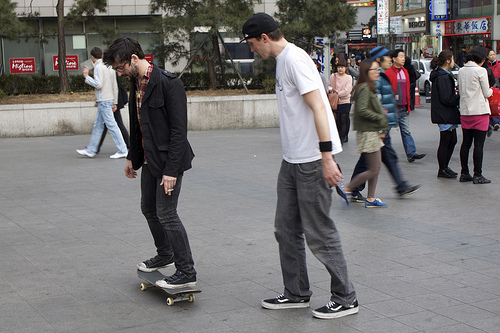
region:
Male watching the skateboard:
[239, 13, 368, 316]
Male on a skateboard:
[102, 38, 200, 305]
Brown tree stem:
[51, 0, 73, 94]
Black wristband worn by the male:
[318, 135, 333, 154]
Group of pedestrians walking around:
[329, 47, 498, 207]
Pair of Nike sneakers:
[261, 290, 361, 318]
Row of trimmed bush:
[1, 68, 217, 95]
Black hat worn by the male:
[239, 13, 283, 43]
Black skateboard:
[134, 263, 199, 303]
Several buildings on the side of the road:
[311, 0, 498, 75]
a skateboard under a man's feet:
[131, 266, 199, 307]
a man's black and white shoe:
[157, 268, 198, 290]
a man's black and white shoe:
[308, 300, 358, 318]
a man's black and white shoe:
[260, 293, 309, 310]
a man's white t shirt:
[278, 43, 343, 163]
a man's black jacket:
[117, 70, 193, 170]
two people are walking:
[78, 47, 127, 157]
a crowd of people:
[331, 46, 496, 208]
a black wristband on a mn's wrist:
[318, 141, 332, 152]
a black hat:
[233, 13, 279, 40]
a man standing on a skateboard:
[101, 36, 204, 308]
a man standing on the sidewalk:
[237, 8, 366, 321]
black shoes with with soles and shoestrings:
[255, 286, 373, 321]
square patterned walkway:
[364, 217, 499, 329]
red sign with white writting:
[6, 50, 46, 77]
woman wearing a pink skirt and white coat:
[456, 41, 495, 189]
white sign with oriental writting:
[438, 13, 498, 36]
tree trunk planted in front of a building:
[38, 0, 78, 99]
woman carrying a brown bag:
[326, 52, 358, 145]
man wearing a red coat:
[386, 42, 426, 162]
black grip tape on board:
[131, 258, 208, 306]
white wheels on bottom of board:
[160, 288, 205, 309]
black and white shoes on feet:
[260, 298, 367, 316]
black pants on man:
[264, 159, 365, 310]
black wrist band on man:
[317, 139, 332, 153]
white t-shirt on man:
[268, 45, 338, 169]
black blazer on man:
[115, 71, 192, 186]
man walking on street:
[80, 42, 122, 156]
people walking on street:
[347, 29, 472, 207]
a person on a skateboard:
[101, 37, 201, 287]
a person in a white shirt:
[237, 5, 362, 319]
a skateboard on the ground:
[133, 265, 202, 305]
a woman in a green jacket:
[341, 57, 387, 212]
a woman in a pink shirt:
[326, 60, 353, 143]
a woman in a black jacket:
[428, 47, 458, 181]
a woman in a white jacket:
[456, 42, 492, 183]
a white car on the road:
[410, 53, 464, 95]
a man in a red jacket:
[383, 48, 428, 163]